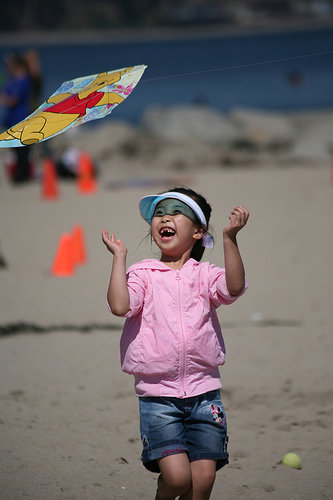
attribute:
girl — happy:
[102, 172, 255, 499]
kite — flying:
[1, 61, 159, 154]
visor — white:
[137, 185, 214, 226]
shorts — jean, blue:
[137, 394, 239, 469]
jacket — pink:
[116, 257, 236, 395]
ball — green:
[265, 448, 319, 484]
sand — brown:
[261, 176, 331, 318]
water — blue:
[149, 35, 292, 102]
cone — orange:
[32, 154, 64, 205]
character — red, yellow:
[63, 74, 130, 118]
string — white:
[148, 39, 330, 91]